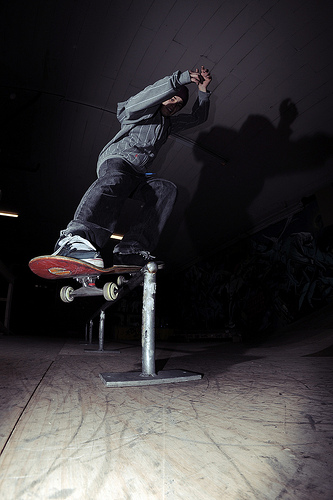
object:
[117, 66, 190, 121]
arm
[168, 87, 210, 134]
arm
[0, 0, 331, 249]
roof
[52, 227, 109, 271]
shoes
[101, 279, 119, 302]
wheel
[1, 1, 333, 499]
background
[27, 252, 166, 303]
skateboard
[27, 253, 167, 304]
board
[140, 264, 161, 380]
leg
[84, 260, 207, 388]
bench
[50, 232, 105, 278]
feet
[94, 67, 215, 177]
sweater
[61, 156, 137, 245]
leg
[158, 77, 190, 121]
head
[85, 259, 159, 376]
rail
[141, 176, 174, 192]
thigh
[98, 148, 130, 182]
thigh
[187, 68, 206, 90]
hand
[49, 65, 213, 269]
boy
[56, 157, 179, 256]
pants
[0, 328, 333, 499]
ground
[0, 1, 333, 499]
photo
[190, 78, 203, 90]
fingers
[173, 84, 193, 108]
hat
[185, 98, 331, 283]
shadow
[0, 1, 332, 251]
ceiling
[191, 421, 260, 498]
mark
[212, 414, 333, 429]
mark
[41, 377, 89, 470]
mark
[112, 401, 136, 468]
mark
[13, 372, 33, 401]
mark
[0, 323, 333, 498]
floor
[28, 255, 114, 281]
bottom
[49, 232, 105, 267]
foot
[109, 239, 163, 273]
foot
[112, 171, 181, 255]
leg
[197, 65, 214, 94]
hand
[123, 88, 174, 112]
stripes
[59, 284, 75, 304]
wheel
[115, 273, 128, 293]
wheel